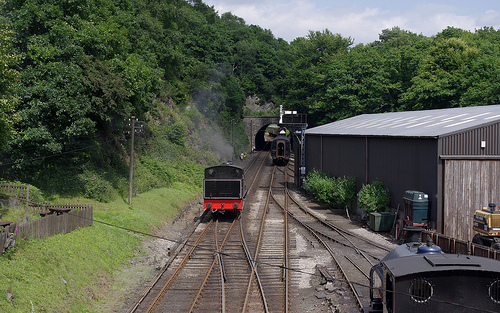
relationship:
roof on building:
[295, 104, 497, 139] [293, 99, 499, 253]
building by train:
[293, 99, 499, 253] [188, 146, 256, 228]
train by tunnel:
[271, 137, 289, 164] [250, 123, 281, 142]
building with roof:
[293, 99, 499, 253] [300, 96, 497, 148]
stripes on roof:
[430, 112, 477, 127] [300, 96, 497, 148]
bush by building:
[298, 163, 356, 215] [293, 99, 499, 253]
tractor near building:
[469, 202, 499, 252] [295, 102, 496, 242]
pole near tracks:
[124, 116, 142, 208] [130, 137, 261, 308]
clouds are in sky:
[200, 0, 499, 48] [188, 0, 499, 51]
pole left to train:
[124, 116, 144, 205] [197, 156, 250, 222]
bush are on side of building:
[302, 167, 391, 218] [293, 99, 499, 253]